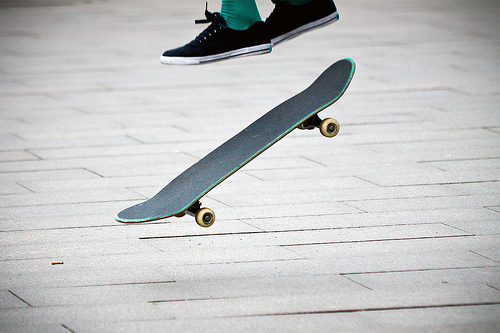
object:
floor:
[0, 0, 498, 333]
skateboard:
[114, 58, 354, 228]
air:
[96, 0, 390, 249]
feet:
[159, 0, 271, 65]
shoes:
[161, 12, 272, 67]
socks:
[219, 0, 263, 30]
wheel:
[195, 208, 215, 228]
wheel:
[173, 211, 185, 217]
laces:
[194, 4, 223, 28]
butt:
[50, 260, 65, 264]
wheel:
[320, 118, 340, 139]